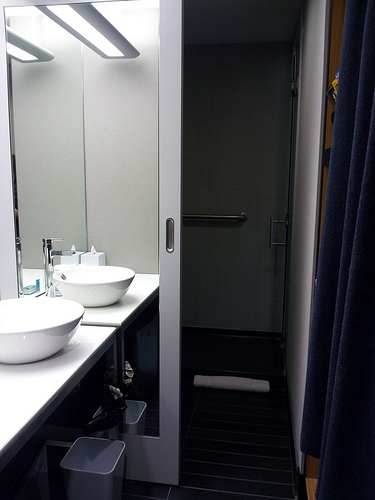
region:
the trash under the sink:
[55, 434, 128, 497]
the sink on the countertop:
[0, 297, 81, 362]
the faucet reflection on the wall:
[34, 235, 77, 293]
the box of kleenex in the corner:
[77, 244, 107, 264]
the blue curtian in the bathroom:
[298, 2, 374, 485]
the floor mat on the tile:
[184, 328, 285, 408]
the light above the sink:
[20, 0, 145, 77]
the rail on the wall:
[176, 208, 250, 225]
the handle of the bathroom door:
[267, 211, 288, 252]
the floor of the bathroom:
[197, 403, 281, 499]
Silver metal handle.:
[162, 215, 176, 256]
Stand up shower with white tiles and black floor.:
[180, 0, 306, 498]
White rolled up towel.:
[190, 371, 274, 394]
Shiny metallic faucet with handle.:
[39, 234, 79, 299]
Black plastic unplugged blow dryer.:
[78, 371, 133, 437]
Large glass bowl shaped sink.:
[0, 292, 84, 365]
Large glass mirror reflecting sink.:
[3, 1, 163, 438]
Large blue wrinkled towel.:
[299, 0, 374, 498]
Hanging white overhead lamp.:
[4, 2, 139, 63]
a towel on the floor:
[194, 375, 272, 392]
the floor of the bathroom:
[212, 429, 273, 487]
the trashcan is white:
[77, 446, 122, 471]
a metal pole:
[201, 214, 239, 224]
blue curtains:
[321, 317, 365, 401]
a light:
[57, 13, 123, 71]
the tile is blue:
[202, 436, 268, 486]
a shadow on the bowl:
[47, 325, 84, 340]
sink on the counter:
[0, 251, 146, 372]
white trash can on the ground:
[54, 436, 133, 496]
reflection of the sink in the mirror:
[40, 251, 142, 313]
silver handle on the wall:
[176, 203, 252, 226]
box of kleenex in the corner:
[79, 243, 112, 269]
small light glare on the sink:
[21, 333, 27, 339]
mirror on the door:
[1, 2, 182, 485]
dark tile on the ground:
[24, 337, 294, 498]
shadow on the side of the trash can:
[77, 436, 113, 460]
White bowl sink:
[0, 293, 84, 366]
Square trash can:
[59, 433, 123, 496]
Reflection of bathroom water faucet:
[37, 235, 77, 297]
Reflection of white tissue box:
[77, 244, 110, 266]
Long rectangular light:
[29, 5, 140, 62]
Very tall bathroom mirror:
[7, 4, 161, 443]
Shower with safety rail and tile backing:
[176, 46, 296, 335]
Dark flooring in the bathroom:
[167, 376, 293, 496]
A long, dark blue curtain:
[289, 2, 372, 491]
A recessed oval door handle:
[159, 217, 178, 256]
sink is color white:
[0, 293, 86, 364]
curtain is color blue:
[300, 3, 371, 495]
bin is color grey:
[56, 428, 123, 494]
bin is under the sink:
[1, 296, 137, 499]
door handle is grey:
[162, 216, 175, 254]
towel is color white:
[189, 370, 271, 397]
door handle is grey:
[263, 212, 288, 252]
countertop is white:
[0, 328, 113, 453]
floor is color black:
[180, 357, 304, 498]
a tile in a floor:
[143, 480, 169, 497]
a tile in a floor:
[166, 484, 192, 499]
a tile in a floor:
[183, 471, 203, 487]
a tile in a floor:
[201, 472, 231, 495]